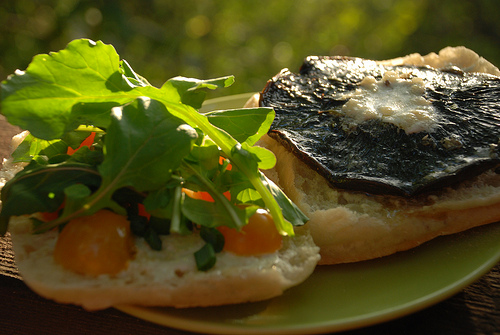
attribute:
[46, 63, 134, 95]
lettuce — GREEN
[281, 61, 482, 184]
mushroom — BROWN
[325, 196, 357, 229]
bread — WHITE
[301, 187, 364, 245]
bread — WHITE, HALVED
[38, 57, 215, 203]
lettuce — GREEN, LEAFY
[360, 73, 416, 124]
base — WHITE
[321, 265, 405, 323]
plate — GREEN, ROUND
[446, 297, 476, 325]
table — BROWN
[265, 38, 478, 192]
mushroom — white stem spot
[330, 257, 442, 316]
plate — round green dinner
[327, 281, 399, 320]
plate — green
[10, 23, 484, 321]
plate — open sandwich , dinner , meatless sandwich